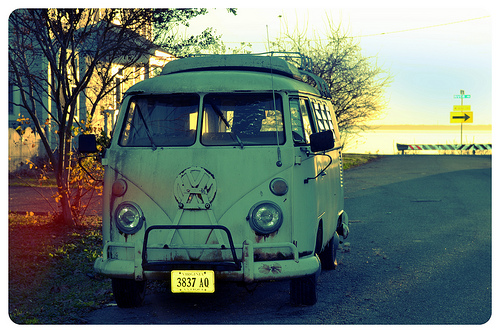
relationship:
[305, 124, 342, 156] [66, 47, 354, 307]
mirror on bus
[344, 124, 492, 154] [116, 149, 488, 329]
water on road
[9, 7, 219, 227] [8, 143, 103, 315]
tree on sidewalk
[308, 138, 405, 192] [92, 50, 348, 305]
ground on vehicle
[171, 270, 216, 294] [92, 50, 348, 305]
license plate on vehicle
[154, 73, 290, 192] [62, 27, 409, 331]
mirror on vehicle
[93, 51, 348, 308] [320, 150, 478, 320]
bus on road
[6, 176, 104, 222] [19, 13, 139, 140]
walkway near home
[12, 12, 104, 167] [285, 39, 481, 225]
house in background